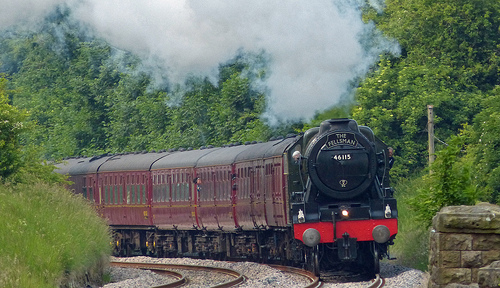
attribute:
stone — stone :
[462, 250, 495, 265]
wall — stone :
[424, 199, 497, 286]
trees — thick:
[324, 7, 498, 233]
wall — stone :
[429, 202, 499, 285]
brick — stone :
[435, 229, 499, 282]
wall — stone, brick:
[444, 232, 495, 280]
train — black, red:
[293, 122, 393, 254]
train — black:
[96, 106, 406, 287]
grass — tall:
[2, 180, 116, 286]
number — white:
[334, 154, 339, 161]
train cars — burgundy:
[64, 136, 294, 245]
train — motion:
[43, 87, 423, 256]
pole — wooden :
[409, 117, 473, 184]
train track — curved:
[128, 257, 221, 281]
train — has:
[42, 116, 397, 278]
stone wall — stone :
[427, 202, 497, 284]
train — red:
[73, 117, 418, 284]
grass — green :
[0, 184, 110, 285]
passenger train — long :
[140, 96, 408, 256]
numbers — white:
[330, 150, 356, 167]